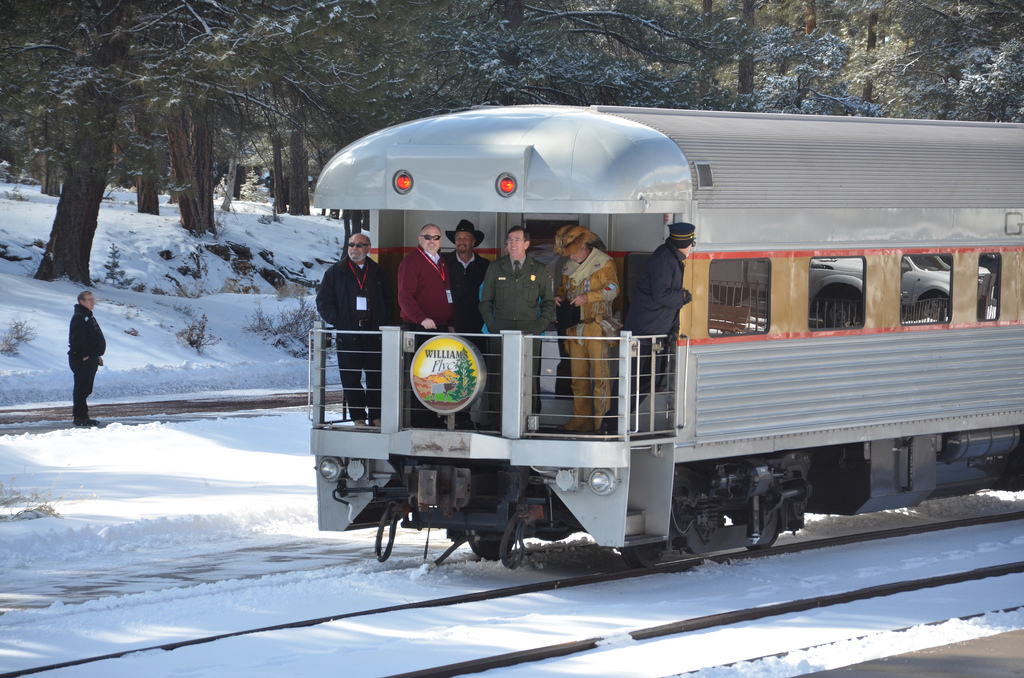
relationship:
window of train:
[807, 244, 872, 339] [259, 106, 1013, 568]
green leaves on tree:
[23, 9, 178, 314] [23, 9, 178, 314]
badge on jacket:
[473, 204, 557, 376] [476, 246, 564, 334]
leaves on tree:
[15, 2, 183, 305] [15, 2, 183, 305]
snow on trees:
[5, 170, 338, 675] [5, 170, 338, 675]